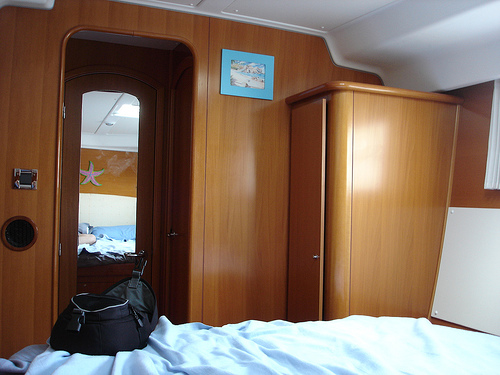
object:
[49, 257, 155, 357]
bag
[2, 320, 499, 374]
bed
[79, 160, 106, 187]
star sign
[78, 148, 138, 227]
wall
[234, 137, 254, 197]
light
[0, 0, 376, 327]
wall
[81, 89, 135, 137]
ceiling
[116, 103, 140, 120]
light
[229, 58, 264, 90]
photo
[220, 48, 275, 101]
frame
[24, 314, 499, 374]
bedcover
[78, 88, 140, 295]
mirror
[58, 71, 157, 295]
door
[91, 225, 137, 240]
pillow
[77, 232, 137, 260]
bed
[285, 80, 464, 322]
closet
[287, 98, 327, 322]
door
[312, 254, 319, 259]
knob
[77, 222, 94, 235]
pillow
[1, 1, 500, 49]
ceiling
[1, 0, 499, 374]
bedroom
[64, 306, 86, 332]
strap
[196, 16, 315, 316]
closet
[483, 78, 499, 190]
curtain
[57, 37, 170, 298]
closet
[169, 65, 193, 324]
door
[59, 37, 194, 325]
corner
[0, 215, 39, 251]
circle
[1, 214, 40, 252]
trim